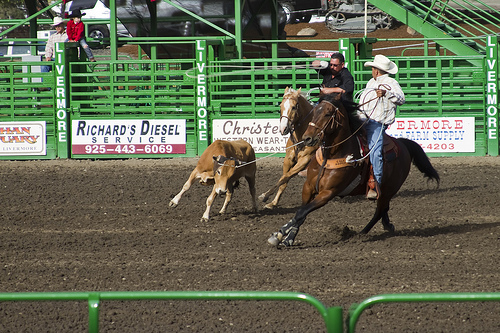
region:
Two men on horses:
[257, 53, 441, 255]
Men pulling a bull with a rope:
[166, 51, 441, 249]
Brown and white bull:
[164, 136, 260, 225]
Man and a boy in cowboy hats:
[39, 8, 95, 95]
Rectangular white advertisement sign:
[67, 115, 189, 157]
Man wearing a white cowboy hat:
[358, 53, 404, 201]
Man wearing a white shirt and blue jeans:
[357, 53, 406, 202]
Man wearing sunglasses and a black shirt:
[311, 52, 355, 112]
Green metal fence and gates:
[0, 40, 499, 163]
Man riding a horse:
[265, 53, 440, 248]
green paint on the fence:
[105, 69, 166, 79]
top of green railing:
[139, 280, 256, 312]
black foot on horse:
[256, 226, 329, 258]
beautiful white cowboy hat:
[359, 43, 436, 83]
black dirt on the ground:
[60, 201, 157, 251]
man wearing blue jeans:
[345, 107, 406, 167]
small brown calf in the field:
[158, 136, 274, 211]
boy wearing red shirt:
[55, 10, 101, 41]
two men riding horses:
[258, 40, 453, 230]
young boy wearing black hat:
[59, 6, 95, 27]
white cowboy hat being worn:
[361, 53, 399, 75]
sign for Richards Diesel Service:
[72, 118, 185, 152]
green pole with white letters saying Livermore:
[196, 38, 207, 154]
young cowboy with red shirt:
[64, 8, 96, 63]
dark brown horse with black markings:
[268, 87, 442, 247]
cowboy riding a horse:
[356, 54, 405, 201]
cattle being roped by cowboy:
[168, 140, 258, 220]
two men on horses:
[258, 52, 440, 254]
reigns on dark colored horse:
[303, 81, 391, 148]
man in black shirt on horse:
[313, 52, 354, 119]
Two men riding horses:
[260, 41, 440, 247]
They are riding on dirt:
[130, 154, 464, 272]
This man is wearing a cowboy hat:
[354, 54, 411, 123]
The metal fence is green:
[15, 60, 280, 139]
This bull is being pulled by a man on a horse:
[162, 130, 278, 224]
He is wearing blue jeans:
[354, 116, 396, 186]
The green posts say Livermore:
[42, 32, 80, 164]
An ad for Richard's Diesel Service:
[72, 113, 189, 149]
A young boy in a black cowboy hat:
[68, 6, 90, 51]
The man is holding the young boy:
[37, 8, 102, 57]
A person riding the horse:
[266, 51, 443, 251]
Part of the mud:
[65, 222, 134, 270]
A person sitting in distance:
[38, 12, 68, 77]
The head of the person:
[327, 49, 347, 74]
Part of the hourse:
[325, 172, 337, 184]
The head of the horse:
[278, 83, 305, 133]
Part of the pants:
[374, 153, 378, 164]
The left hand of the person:
[374, 85, 386, 98]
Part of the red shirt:
[71, 27, 81, 37]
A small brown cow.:
[168, 138, 261, 223]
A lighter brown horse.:
[258, 84, 379, 213]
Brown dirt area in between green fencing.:
[3, 156, 499, 331]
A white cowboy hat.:
[361, 53, 399, 75]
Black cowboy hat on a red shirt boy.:
[65, 9, 85, 19]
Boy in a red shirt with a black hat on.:
[62, 8, 97, 66]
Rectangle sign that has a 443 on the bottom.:
[68, 117, 186, 155]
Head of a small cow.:
[213, 156, 238, 198]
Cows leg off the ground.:
[166, 170, 194, 208]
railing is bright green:
[72, 72, 109, 78]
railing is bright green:
[116, 80, 148, 86]